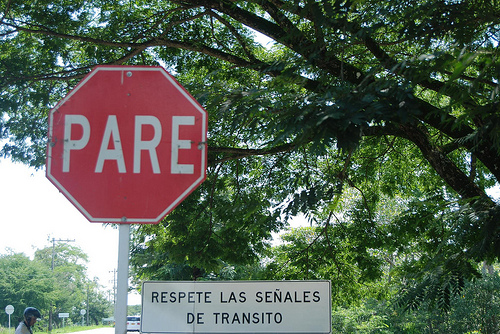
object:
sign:
[45, 65, 208, 224]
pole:
[114, 222, 132, 334]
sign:
[141, 280, 334, 333]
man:
[13, 306, 43, 334]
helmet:
[22, 307, 43, 322]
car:
[125, 315, 142, 332]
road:
[64, 324, 142, 334]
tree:
[0, 0, 500, 319]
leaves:
[338, 131, 363, 153]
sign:
[58, 313, 69, 318]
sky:
[0, 156, 120, 303]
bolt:
[126, 71, 132, 77]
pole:
[49, 237, 77, 334]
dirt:
[47, 136, 69, 149]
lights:
[137, 323, 141, 326]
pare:
[62, 114, 195, 174]